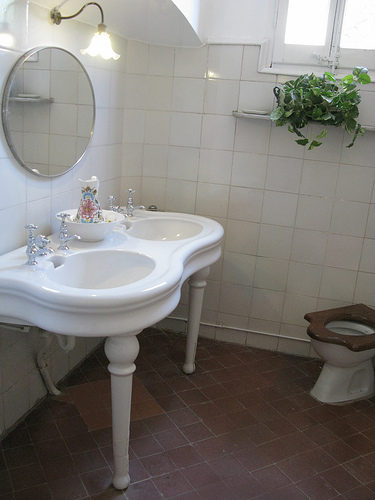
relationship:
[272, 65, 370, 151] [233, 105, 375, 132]
plant on shelf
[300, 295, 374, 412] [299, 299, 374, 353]
toilet has seat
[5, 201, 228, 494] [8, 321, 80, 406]
sink has plumbing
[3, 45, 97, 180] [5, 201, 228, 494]
mirror above sink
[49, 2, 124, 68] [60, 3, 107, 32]
light has neck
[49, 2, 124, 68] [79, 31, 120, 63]
light has shade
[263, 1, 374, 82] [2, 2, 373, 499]
window in bathroom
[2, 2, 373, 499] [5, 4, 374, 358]
bathroom has walls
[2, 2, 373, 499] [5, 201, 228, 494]
bathroom has sink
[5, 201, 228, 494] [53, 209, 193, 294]
sink has basins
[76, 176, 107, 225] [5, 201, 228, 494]
pitcher on sink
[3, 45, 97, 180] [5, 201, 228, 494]
mirror over sink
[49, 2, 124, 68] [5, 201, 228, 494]
light over sink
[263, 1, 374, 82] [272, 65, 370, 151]
window over plant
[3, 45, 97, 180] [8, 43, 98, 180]
mirror has frame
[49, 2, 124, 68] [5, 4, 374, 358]
light on walls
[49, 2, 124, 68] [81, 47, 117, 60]
light has edge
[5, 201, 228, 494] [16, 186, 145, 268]
sink has faucets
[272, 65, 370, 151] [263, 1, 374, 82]
plant below window